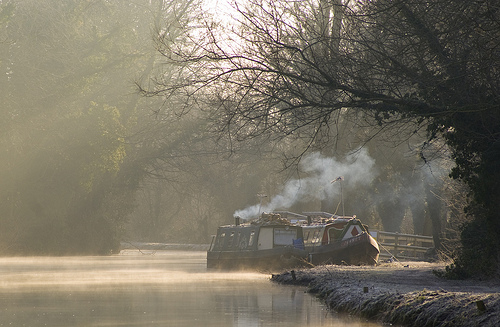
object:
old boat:
[203, 208, 380, 276]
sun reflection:
[0, 249, 276, 289]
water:
[1, 241, 376, 325]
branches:
[137, 2, 497, 159]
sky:
[3, 4, 497, 202]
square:
[338, 218, 360, 249]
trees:
[2, 6, 199, 261]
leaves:
[2, 2, 199, 242]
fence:
[346, 195, 471, 302]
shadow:
[212, 288, 323, 316]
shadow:
[355, 268, 478, 285]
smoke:
[231, 150, 386, 221]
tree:
[227, 15, 455, 144]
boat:
[204, 192, 388, 272]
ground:
[329, 260, 459, 292]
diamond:
[348, 225, 360, 237]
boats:
[199, 205, 384, 279]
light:
[328, 258, 440, 271]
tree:
[2, 7, 211, 256]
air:
[45, 97, 382, 212]